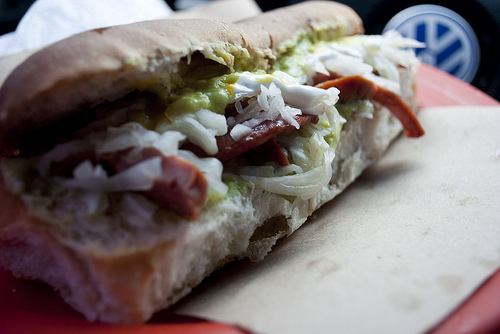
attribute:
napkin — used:
[188, 104, 497, 332]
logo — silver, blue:
[381, 3, 479, 89]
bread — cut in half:
[1, 0, 416, 322]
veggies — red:
[106, 121, 156, 154]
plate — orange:
[0, 50, 500, 332]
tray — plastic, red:
[0, 62, 498, 332]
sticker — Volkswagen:
[313, 30, 468, 146]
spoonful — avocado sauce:
[137, 67, 295, 152]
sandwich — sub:
[55, 48, 353, 233]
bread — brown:
[47, 217, 187, 320]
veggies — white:
[111, 96, 318, 196]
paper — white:
[331, 198, 446, 293]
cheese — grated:
[139, 86, 306, 176]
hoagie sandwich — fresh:
[5, 4, 422, 324]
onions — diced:
[256, 72, 300, 130]